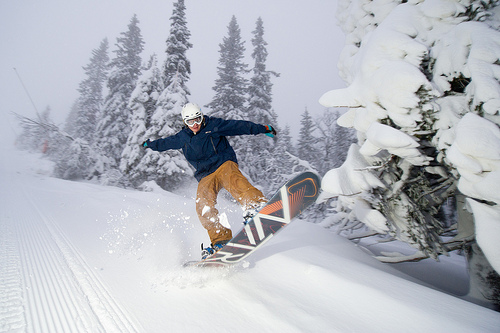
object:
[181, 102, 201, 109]
top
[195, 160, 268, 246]
pants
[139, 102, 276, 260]
man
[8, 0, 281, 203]
trees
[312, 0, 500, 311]
tree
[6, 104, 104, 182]
tree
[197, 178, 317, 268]
stripes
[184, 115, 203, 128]
goggles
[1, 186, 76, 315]
lines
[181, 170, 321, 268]
board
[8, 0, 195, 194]
trees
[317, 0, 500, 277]
snow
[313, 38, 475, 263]
branches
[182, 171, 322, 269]
snow board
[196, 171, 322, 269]
bottom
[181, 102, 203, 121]
helmet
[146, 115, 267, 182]
jacket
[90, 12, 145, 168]
pine tree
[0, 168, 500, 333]
snow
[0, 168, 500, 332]
ground